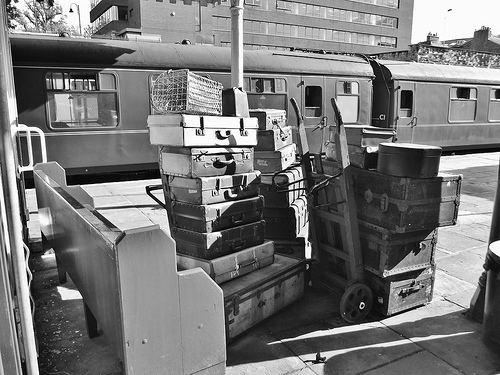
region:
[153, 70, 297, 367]
luggage piled on ground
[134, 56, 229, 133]
cage on top of luggage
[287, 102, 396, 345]
cart is behind luggage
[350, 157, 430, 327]
three chests on cart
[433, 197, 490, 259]
grey sidewalk behind cart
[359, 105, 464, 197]
circular box on chests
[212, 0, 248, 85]
grey pole behind luggage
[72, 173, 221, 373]
bench next to luggage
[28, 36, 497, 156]
dark train behind luggage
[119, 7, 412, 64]
large building behind train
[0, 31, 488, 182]
train carts on railway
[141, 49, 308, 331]
several stacked suitcases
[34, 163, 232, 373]
bench on floor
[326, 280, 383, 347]
wheel of push cart on ground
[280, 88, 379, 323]
cart with suitcases stacked on it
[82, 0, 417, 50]
commercial building with several windows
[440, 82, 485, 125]
window of side train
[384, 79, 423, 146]
side door of train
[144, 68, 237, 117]
wire cage case on suitcase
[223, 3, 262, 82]
light pole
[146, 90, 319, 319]
a stack of suitcases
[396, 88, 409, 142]
a door of the train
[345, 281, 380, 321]
a wheel on a dolly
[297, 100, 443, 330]
a dolly with suitcases on it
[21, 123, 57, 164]
handles on the door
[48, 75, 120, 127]
a window of the train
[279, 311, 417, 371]
the sidewalk under the suitcases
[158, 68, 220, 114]
a wire cage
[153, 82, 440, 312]
many suitcases in front of a train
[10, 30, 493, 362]
stacked luggage at an old train station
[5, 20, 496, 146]
older train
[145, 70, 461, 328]
stacked vintage luggage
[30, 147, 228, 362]
bench behind the suitcases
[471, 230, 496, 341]
the side of a trashcan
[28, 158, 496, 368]
large tiles on the platform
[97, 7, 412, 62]
building behind the train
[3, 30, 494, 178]
vintage train cars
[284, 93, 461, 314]
luggage stacked on a dolly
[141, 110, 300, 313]
many pieces of luggage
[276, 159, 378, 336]
dark cart behind luggage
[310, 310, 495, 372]
shadows cast on ground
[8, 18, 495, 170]
black train behind luggage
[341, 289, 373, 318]
black wheel on cart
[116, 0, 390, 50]
large building behind train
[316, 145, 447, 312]
three chests on cart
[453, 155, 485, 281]
light grey sidewalk around cart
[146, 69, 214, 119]
small wire case above luggage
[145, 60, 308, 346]
A stack of suitcases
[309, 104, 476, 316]
A stack of trunks with boxes on top on a hand truck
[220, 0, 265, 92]
A tall metal pole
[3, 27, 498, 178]
Two parked train cars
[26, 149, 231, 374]
A painted wooden bench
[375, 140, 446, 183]
A large hat box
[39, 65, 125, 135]
A train window that shows the other side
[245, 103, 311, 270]
A stack of luggage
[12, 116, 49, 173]
Two white metal handles